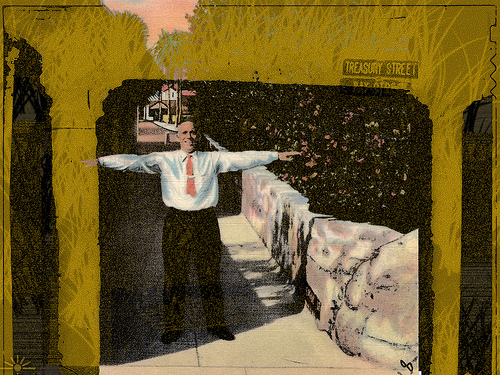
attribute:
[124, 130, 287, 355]
man — standing, spread, old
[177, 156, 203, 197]
tie — red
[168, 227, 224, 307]
pants — black, dark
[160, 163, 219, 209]
shirt — white